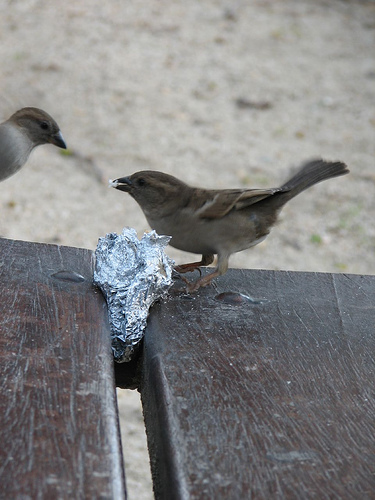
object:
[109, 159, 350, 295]
bird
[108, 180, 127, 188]
foil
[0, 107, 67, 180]
bird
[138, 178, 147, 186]
eye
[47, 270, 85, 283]
screw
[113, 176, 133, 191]
beak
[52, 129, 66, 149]
beak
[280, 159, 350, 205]
tail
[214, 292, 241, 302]
bolt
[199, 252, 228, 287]
leg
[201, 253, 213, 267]
leg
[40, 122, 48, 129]
eye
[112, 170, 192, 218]
head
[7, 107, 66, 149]
head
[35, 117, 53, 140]
face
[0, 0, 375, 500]
ground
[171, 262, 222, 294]
feet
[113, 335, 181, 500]
hole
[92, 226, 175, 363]
foil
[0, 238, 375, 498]
table